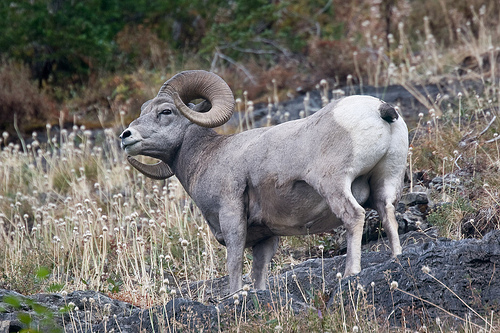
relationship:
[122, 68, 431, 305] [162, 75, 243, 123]
ram has horn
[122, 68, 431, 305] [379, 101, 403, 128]
ram has tail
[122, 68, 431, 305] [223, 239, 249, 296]
ram has front leg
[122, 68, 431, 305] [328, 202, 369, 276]
ram has rear leg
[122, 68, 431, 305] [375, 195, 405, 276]
ram has rear leg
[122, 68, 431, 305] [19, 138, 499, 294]
ram standing in field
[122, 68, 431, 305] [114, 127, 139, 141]
ram has nose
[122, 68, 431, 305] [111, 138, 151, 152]
ram has mouth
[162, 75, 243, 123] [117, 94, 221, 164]
horn on top of head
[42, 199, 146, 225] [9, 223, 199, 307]
buds on plants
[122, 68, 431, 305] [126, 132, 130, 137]
ram has nostril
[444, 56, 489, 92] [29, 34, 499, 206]
rock on hillside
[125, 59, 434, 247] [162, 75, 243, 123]
sheep has horn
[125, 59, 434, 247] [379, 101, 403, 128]
sheep has tail